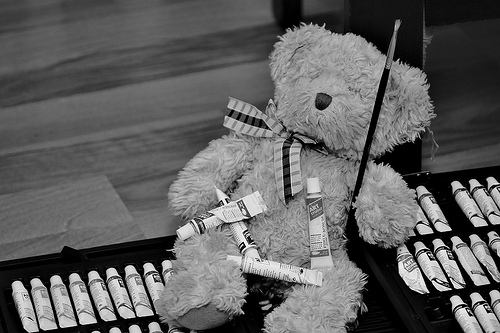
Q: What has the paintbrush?
A: Teddy bear.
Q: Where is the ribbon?
A: Around neck.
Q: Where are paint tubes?
A: In tray.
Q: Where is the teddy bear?
A: On tray.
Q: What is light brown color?
A: Teddy bear.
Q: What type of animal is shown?
A: Bear.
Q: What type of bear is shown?
A: Teddy bear.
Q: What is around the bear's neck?
A: Bow.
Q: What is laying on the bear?
A: Paint tubes.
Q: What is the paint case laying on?
A: Floor.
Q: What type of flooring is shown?
A: Hardwood.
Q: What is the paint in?
A: Tubes.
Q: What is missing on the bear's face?
A: Eyes.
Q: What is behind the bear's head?
A: Chair leg.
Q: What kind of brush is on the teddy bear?
A: A paint brush.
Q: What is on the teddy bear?
A: Tubes of paint.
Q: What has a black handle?
A: The paint brush.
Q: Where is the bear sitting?
A: On a paint set.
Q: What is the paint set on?
A: A wooden floor.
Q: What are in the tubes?
A: Paint.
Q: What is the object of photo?
A: Teddy bear.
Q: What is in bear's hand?
A: Paintbrush.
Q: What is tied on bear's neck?
A: Bow.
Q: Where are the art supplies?
A: On table.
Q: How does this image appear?
A: Black and white.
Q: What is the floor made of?
A: Wood.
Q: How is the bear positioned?
A: Leaning.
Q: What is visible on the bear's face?
A: Nose.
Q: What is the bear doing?
A: Painting.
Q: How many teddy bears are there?
A: One.